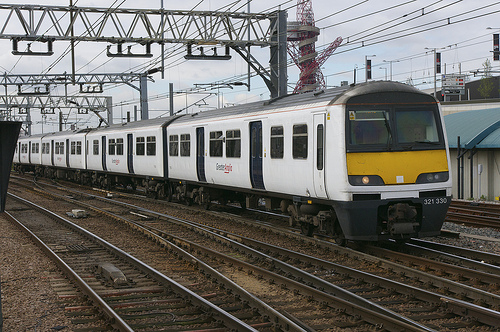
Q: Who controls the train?
A: The engineer.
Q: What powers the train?
A: Electricity.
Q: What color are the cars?
A: Mostly white.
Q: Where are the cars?
A: On a train track.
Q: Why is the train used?
A: Transportation.